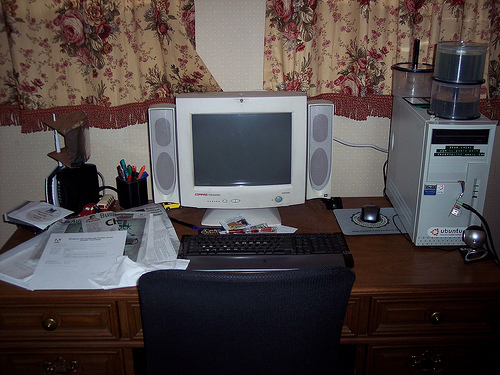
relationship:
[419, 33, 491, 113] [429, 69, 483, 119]
cd in case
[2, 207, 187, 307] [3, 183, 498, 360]
papers on desk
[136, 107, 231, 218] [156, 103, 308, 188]
speakers on computer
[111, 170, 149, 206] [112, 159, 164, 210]
cup with pens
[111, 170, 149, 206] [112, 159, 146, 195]
cup with pencils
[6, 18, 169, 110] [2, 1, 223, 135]
curtain over window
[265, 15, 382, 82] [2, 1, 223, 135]
curtain over window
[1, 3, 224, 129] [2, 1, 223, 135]
blanket over window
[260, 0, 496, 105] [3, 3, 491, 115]
curtain with flowers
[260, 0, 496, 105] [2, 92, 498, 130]
curtain with fringe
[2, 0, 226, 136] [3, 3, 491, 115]
curtain with flowers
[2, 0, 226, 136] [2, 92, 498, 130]
curtain with fringe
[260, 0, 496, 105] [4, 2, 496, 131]
curtain covering windows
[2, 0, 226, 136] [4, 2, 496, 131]
curtain covering windows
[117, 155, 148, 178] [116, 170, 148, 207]
pencils in holder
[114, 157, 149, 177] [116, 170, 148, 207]
pens in holder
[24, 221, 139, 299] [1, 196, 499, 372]
papers sitting on desk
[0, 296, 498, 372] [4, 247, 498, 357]
drawers in desk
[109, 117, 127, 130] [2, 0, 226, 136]
edge of curtain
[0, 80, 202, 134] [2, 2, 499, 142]
fringes on curtains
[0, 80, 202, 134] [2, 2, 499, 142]
fringes at bottom of curtains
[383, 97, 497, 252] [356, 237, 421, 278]
computer tower on desk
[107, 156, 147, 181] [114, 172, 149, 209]
pens in black container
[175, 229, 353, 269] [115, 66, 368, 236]
keyboard in front of monitor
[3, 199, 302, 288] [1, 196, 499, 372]
papers on desk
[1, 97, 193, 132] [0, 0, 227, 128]
fringe on curtains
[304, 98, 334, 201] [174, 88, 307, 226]
speaker on computer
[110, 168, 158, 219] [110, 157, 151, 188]
container has pens